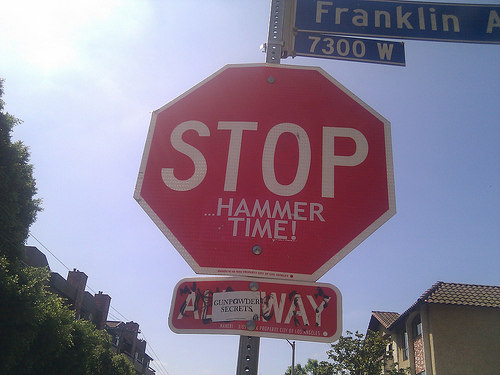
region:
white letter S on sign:
[157, 115, 212, 193]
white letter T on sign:
[214, 111, 257, 196]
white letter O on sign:
[259, 118, 312, 198]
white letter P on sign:
[315, 121, 373, 201]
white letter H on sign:
[211, 199, 237, 217]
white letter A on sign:
[232, 195, 251, 217]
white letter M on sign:
[248, 195, 276, 219]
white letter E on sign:
[287, 196, 307, 220]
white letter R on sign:
[308, 198, 326, 229]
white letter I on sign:
[241, 210, 255, 239]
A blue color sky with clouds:
[57, 27, 127, 148]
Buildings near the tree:
[38, 247, 150, 342]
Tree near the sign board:
[8, 305, 105, 354]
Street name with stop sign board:
[266, 0, 498, 55]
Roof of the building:
[437, 275, 496, 300]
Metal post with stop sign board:
[145, 59, 417, 367]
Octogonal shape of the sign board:
[122, 62, 419, 273]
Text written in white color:
[170, 115, 370, 249]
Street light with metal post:
[288, 342, 306, 365]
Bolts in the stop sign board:
[250, 68, 279, 269]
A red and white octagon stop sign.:
[132, 64, 397, 287]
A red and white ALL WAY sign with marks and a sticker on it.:
[165, 277, 343, 344]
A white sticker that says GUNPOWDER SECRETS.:
[210, 290, 262, 322]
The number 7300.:
[306, 33, 365, 59]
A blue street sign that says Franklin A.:
[295, 1, 499, 45]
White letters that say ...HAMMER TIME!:
[203, 195, 325, 244]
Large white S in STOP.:
[160, 120, 212, 191]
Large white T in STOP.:
[214, 119, 258, 191]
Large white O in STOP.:
[262, 119, 312, 196]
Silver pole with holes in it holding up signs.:
[234, 333, 259, 374]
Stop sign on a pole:
[126, 55, 398, 283]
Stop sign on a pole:
[186, 45, 356, 140]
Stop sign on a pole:
[146, 213, 379, 368]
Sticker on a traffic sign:
[207, 289, 264, 323]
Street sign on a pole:
[261, 5, 493, 87]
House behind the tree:
[367, 306, 470, 373]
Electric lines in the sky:
[35, 236, 175, 373]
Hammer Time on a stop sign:
[194, 178, 316, 257]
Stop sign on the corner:
[131, 61, 396, 266]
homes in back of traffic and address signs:
[7, 1, 492, 366]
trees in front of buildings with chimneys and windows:
[0, 105, 151, 371]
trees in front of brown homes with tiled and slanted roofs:
[295, 276, 495, 371]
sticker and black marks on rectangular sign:
[167, 276, 341, 339]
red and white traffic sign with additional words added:
[140, 65, 395, 277]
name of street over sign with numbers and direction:
[286, 0, 496, 62]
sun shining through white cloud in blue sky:
[2, 0, 492, 367]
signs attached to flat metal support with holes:
[235, 0, 285, 370]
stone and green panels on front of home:
[365, 311, 437, 369]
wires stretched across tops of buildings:
[22, 230, 162, 370]